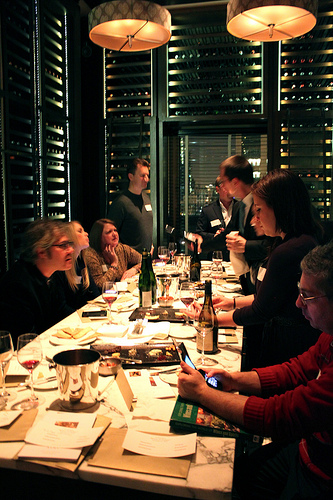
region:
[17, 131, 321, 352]
three wine bottles on the table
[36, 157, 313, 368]
nine people in the shot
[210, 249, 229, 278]
a glass of wine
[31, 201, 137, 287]
these people look like they are not hearing anything good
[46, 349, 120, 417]
a metal container on the table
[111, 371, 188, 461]
items on the table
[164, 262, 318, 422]
this person is observing their cell phone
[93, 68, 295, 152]
windows in the background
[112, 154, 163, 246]
this man is standing up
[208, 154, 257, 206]
this man is saying something to the other people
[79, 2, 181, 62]
gray lights in a restaurant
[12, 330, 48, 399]
nearly empty wine glass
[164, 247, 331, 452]
man checking phone at dinner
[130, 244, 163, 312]
bottle of wine on table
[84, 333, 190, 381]
half empty appetizer plate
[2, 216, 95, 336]
man with gray hair and woman with blonde hair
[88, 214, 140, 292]
older lady listening instensely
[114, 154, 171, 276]
man in gray sweater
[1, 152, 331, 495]
dinner party with many guests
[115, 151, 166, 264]
man wearing white nametag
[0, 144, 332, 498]
"People are standing and sitting around a table"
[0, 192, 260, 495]
"A long table is pictured here"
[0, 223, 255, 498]
"The table is cluttered"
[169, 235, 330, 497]
"He is looking at his phone"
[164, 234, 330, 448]
"His arms and hands are on a book"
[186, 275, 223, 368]
"A bottle of wine"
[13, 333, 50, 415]
"A glass of wine"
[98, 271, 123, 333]
"The wine is red"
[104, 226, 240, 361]
"Several bottles of wine"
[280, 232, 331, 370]
"He is wearing glasses"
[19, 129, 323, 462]
a group of people are dining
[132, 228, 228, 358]
wine bottles are on the table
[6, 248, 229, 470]
several papers are on the table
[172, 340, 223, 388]
this man is looking at this cell phone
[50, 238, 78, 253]
this man is wearing glasses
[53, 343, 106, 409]
a chilling bucket for wine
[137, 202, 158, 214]
the man is wearing a name tag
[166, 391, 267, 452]
this man has a text book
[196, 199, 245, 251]
the man is wearing a black blazer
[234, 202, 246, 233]
the man is wearing a tie